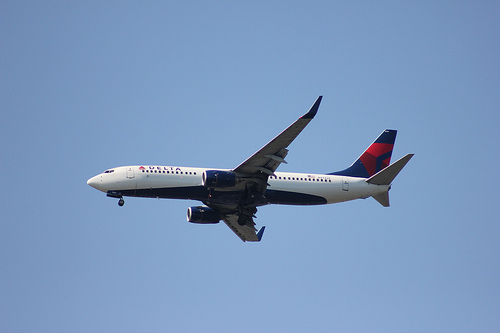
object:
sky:
[3, 0, 498, 325]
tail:
[325, 128, 397, 179]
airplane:
[86, 95, 415, 243]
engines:
[186, 170, 238, 224]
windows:
[140, 168, 145, 172]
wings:
[202, 203, 266, 243]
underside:
[160, 185, 274, 198]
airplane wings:
[232, 95, 323, 177]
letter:
[157, 166, 164, 172]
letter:
[174, 165, 183, 173]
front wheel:
[105, 190, 126, 207]